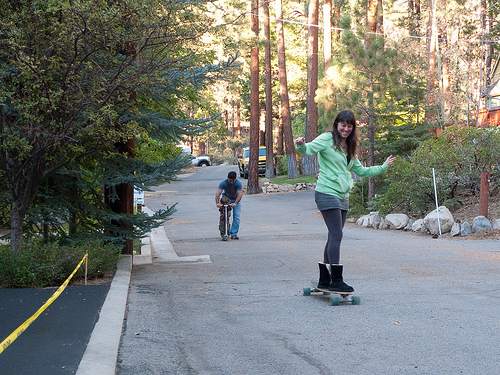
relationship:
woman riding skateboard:
[303, 113, 377, 286] [311, 279, 360, 308]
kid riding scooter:
[218, 198, 233, 229] [217, 229, 236, 241]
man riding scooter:
[218, 170, 252, 205] [217, 229, 236, 241]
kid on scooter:
[218, 198, 233, 229] [217, 229, 236, 241]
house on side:
[437, 87, 500, 167] [409, 20, 445, 205]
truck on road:
[240, 139, 282, 172] [236, 149, 292, 296]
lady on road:
[303, 113, 377, 286] [236, 149, 292, 296]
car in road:
[235, 132, 277, 180] [236, 149, 292, 296]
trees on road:
[37, 36, 241, 167] [236, 149, 292, 296]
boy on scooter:
[215, 198, 239, 243] [217, 229, 236, 241]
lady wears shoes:
[303, 113, 377, 286] [318, 262, 354, 293]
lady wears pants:
[303, 113, 377, 286] [317, 215, 348, 261]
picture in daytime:
[23, 19, 493, 341] [201, 32, 371, 79]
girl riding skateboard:
[309, 113, 373, 206] [311, 279, 360, 308]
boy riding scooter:
[215, 198, 239, 243] [217, 229, 236, 241]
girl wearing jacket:
[309, 113, 373, 206] [315, 143, 366, 195]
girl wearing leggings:
[309, 113, 373, 206] [317, 215, 348, 261]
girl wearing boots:
[309, 113, 373, 206] [318, 262, 354, 293]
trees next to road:
[37, 36, 241, 167] [236, 149, 292, 296]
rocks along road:
[370, 207, 482, 231] [236, 149, 292, 296]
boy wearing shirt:
[215, 198, 239, 243] [221, 210, 235, 220]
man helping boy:
[218, 170, 252, 205] [215, 198, 239, 243]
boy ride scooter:
[215, 198, 239, 243] [217, 229, 236, 241]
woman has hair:
[303, 113, 377, 286] [343, 109, 360, 136]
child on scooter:
[218, 198, 233, 229] [217, 229, 236, 241]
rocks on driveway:
[370, 207, 482, 231] [4, 288, 67, 371]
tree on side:
[13, 11, 188, 262] [409, 20, 445, 205]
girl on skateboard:
[309, 113, 373, 206] [311, 279, 360, 308]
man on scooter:
[218, 170, 252, 205] [217, 229, 236, 241]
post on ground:
[427, 170, 446, 244] [389, 225, 500, 259]